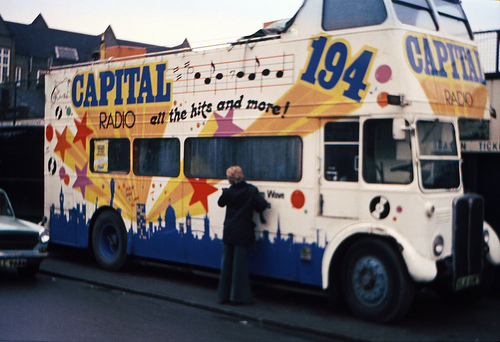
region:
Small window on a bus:
[85, 136, 125, 173]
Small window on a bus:
[131, 126, 175, 179]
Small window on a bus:
[183, 133, 318, 183]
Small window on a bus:
[317, 111, 358, 141]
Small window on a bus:
[318, 143, 350, 183]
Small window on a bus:
[357, 112, 415, 194]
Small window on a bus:
[411, 118, 453, 150]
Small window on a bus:
[415, 158, 470, 188]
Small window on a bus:
[321, 1, 396, 35]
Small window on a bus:
[392, 4, 437, 29]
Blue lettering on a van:
[68, 69, 88, 106]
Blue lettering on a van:
[83, 71, 107, 101]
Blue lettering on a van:
[93, 65, 113, 105]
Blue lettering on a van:
[110, 61, 135, 110]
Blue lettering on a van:
[121, 66, 138, 116]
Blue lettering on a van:
[149, 58, 179, 98]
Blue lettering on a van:
[397, 28, 427, 70]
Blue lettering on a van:
[421, 33, 443, 88]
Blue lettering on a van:
[442, 41, 489, 88]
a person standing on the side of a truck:
[202, 161, 271, 311]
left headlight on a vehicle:
[13, 217, 56, 274]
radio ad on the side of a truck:
[37, 2, 449, 310]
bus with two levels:
[35, 2, 497, 324]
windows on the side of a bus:
[77, 116, 316, 185]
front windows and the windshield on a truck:
[318, 99, 499, 196]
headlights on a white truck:
[418, 192, 453, 303]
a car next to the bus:
[2, 195, 53, 280]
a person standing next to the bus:
[208, 160, 262, 296]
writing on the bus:
[63, 73, 166, 103]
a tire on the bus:
[339, 233, 400, 311]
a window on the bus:
[185, 133, 307, 177]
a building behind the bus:
[2, 25, 83, 73]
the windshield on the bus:
[416, 123, 458, 182]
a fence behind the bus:
[6, 80, 45, 135]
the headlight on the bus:
[434, 235, 444, 252]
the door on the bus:
[321, 116, 356, 216]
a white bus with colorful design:
[27, 24, 498, 331]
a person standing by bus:
[176, 123, 318, 340]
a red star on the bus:
[69, 110, 96, 178]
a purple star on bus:
[65, 159, 122, 219]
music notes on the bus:
[170, 52, 312, 127]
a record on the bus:
[347, 194, 393, 239]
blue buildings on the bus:
[42, 179, 325, 299]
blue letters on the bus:
[64, 58, 189, 120]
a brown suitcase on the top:
[93, 30, 173, 83]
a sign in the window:
[79, 131, 128, 191]